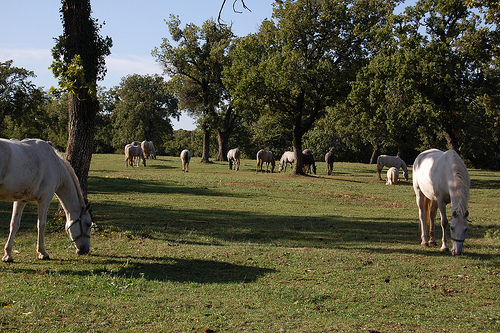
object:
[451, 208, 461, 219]
ear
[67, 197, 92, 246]
bridle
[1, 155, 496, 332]
grass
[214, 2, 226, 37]
branch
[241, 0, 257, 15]
branch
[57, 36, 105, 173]
tree trunk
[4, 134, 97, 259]
white horses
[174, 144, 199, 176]
white horses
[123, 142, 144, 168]
horse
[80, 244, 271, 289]
shadow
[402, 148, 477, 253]
white horse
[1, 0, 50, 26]
blue sky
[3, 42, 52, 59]
clouds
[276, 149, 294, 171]
horse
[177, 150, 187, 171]
horse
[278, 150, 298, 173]
horse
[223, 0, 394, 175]
tree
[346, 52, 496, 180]
tree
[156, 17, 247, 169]
tree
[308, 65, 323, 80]
leaf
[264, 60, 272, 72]
leaf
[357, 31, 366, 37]
leaf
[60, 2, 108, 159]
trunk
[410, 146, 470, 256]
white horse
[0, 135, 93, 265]
white horse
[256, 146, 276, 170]
white horse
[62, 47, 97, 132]
tree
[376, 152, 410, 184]
whitehorse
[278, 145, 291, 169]
whitehorse